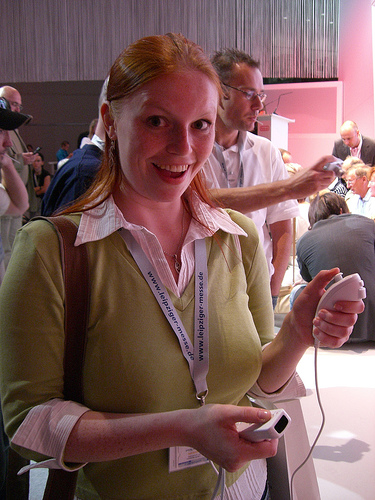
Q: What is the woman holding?
A: A controller.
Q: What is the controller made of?
A: Plastic.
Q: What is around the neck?
A: A lanyard.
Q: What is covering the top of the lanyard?
A: The collar.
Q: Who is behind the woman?
A: A man.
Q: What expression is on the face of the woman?
A: Happy.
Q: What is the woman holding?
A: A controller.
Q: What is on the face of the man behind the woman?
A: Glasses.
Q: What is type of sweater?
A: V neck.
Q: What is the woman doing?
A: Acting surprised.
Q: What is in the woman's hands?
A: Controllers.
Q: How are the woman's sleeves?
A: Folded.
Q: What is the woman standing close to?
A: A table.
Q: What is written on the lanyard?
A: Company name.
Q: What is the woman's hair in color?
A: Ginger.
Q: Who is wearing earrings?
A: The woman.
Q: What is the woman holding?
A: A controller.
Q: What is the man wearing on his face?
A: Glasses.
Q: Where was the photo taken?
A: A convention.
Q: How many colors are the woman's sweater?
A: One.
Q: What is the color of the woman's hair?
A: Red.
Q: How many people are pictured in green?
A: One.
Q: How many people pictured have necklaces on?
A: One.